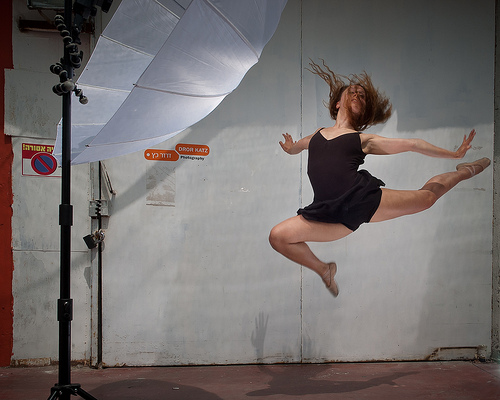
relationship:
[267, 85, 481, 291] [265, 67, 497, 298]
light skinned on lady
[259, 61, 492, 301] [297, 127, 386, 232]
woman with black outfit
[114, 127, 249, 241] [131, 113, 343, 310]
signs on a wall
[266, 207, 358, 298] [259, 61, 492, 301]
right leg of a woman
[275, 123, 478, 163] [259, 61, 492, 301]
arms of a leaping woman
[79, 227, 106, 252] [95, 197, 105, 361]
padlock on pole